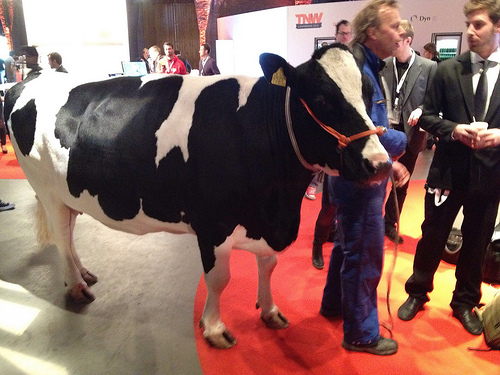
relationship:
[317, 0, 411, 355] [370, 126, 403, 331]
man holding leash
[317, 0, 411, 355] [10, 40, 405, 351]
man guiding cow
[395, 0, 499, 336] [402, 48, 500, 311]
man has man in suit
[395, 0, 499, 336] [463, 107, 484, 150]
man holding cup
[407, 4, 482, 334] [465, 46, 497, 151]
man wearing black tie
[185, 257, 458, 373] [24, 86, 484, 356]
red carpet on floor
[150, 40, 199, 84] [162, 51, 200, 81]
man wearing red hoodie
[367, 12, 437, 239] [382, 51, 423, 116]
man wearing lanyard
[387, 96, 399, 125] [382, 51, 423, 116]
tag on lanyard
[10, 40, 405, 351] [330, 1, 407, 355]
cow next to man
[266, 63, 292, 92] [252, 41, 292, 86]
tag in ear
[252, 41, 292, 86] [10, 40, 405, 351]
ear of cow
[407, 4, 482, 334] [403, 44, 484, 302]
man in suit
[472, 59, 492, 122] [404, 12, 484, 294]
black tie on man